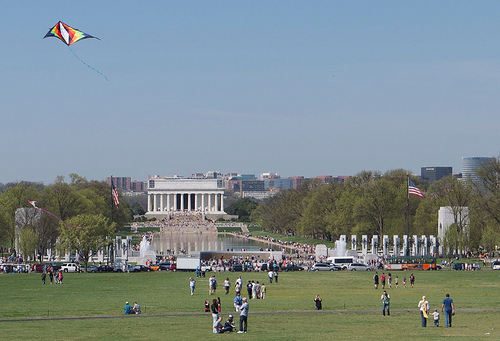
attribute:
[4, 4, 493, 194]
sky — blue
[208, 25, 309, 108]
clouds — white